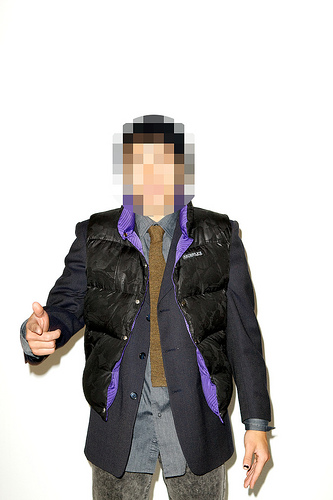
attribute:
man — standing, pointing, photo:
[20, 113, 274, 499]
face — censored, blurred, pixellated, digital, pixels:
[129, 142, 174, 212]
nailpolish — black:
[241, 460, 250, 470]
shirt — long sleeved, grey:
[23, 218, 273, 420]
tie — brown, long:
[146, 224, 169, 390]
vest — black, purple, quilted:
[83, 199, 232, 422]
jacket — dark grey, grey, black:
[27, 216, 272, 419]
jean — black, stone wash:
[88, 456, 225, 500]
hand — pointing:
[24, 302, 62, 358]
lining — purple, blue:
[106, 207, 222, 420]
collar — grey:
[131, 209, 178, 238]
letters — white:
[179, 249, 204, 261]